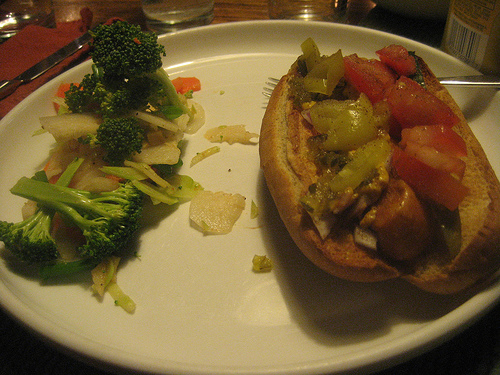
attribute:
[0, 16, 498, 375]
plate — white, shiny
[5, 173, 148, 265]
broccoli — green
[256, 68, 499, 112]
fork — shiny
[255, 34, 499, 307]
sandwich — large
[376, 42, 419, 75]
tomato — red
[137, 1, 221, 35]
glass — drinking glass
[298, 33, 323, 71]
pepper — hot, nice, green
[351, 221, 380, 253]
onion — small, white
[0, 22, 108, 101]
knife — silver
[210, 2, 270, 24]
surface — brown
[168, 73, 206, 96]
carrot — orange